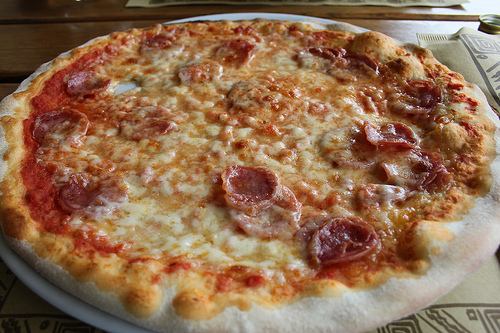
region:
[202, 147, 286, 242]
a pepperoni on the pizza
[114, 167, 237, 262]
melted cheese on the pizza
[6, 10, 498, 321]
a large cooked pizza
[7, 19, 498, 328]
a cheese and meat pizza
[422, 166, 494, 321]
the crust of the pizza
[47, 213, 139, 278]
red pizza sauce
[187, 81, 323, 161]
mozzarella cheese on pizza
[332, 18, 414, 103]
air bubbles in the crust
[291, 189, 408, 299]
pepperoni stacked on top of each other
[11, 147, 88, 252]
red pizza sauce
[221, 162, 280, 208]
A large, red pepperoni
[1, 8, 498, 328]
A fully baked pizza with lots of cheese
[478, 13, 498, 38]
A beer bottle cap that's off the bottle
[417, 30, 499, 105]
A napkin with line art designs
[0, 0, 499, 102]
A wooden table with food on it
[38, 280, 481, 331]
Puffy crust around the baked pizza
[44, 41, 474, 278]
A lot of melted mozzarelle cheese on the baked pizza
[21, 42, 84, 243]
A concentrated dose of tomato sauce on the side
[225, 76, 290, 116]
A pepperoni slice covered in melted cheese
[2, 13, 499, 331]
A giant pizza on a white platter underneath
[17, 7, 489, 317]
a cheese and pepperoni pizza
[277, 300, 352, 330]
a white crust on a pizza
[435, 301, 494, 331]
brown design on a table top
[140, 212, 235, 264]
white cheese on a pizza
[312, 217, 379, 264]
small pieces of pepperoni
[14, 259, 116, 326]
the edge of a white plate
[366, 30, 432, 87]
the bubbles in the pizza crust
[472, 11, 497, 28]
a brass colored lid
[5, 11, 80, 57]
brown slats in a wooden table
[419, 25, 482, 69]
a brown table cloth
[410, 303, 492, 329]
aztec design on the tablecloth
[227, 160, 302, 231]
pink piece of ham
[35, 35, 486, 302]
pizza covered in cheese and ham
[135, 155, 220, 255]
bubbling cheese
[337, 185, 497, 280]
cooked piece of pizza crust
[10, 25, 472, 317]
pizza on a white plate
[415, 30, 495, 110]
napkin with aztec design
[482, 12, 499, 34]
bottle cap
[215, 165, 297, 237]
two pieces of ham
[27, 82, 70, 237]
tomato pizza sauce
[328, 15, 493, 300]
Browned pizza crust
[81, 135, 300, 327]
Mozzerella cheese and sauce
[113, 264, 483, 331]
Under cooked pizza crust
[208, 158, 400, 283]
Pepperoni pizza topping and cheese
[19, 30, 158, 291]
Lots of sauce and pepperoni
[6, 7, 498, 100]
Wooden slat table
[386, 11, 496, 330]
Decoration on the placemat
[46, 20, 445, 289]
Lots of cheese and pepperoni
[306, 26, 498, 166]
Yummy carmelized cheese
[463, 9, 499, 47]
Small container on the table